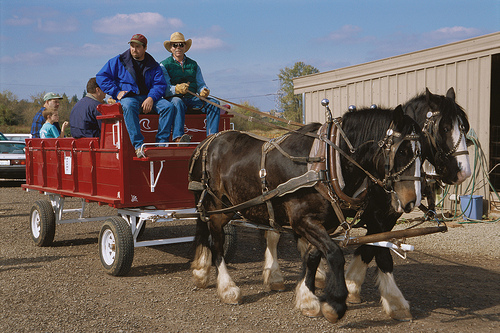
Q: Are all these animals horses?
A: Yes, all the animals are horses.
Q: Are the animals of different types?
A: No, all the animals are horses.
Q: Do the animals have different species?
A: No, all the animals are horses.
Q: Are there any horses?
A: Yes, there are horses.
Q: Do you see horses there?
A: Yes, there are horses.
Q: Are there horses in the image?
A: Yes, there are horses.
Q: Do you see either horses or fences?
A: Yes, there are horses.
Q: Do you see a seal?
A: No, there are no seals.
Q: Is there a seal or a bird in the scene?
A: No, there are no seals or birds.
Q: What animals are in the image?
A: The animals are horses.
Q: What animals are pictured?
A: The animals are horses.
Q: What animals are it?
A: The animals are horses.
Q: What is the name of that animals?
A: These are horses.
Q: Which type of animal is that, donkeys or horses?
A: These are horses.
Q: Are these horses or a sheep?
A: These are horses.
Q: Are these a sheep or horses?
A: These are horses.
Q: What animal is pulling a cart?
A: The horses are pulling a cart.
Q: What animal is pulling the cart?
A: The horses are pulling a cart.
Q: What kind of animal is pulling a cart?
A: The animals are horses.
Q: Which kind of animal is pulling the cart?
A: The animals are horses.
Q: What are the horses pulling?
A: The horses are pulling a cart.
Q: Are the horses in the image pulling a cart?
A: Yes, the horses are pulling a cart.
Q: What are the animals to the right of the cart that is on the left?
A: The animals are horses.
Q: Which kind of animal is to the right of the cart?
A: The animals are horses.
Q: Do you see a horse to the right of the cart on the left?
A: Yes, there are horses to the right of the cart.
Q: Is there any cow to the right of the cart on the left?
A: No, there are horses to the right of the cart.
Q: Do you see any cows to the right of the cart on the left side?
A: No, there are horses to the right of the cart.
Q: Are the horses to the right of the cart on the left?
A: Yes, the horses are to the right of the cart.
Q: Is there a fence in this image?
A: No, there are no fences.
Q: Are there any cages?
A: No, there are no cages.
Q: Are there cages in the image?
A: No, there are no cages.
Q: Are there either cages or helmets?
A: No, there are no cages or helmets.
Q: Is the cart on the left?
A: Yes, the cart is on the left of the image.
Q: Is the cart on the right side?
A: No, the cart is on the left of the image.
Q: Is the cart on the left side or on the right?
A: The cart is on the left of the image.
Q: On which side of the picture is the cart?
A: The cart is on the left of the image.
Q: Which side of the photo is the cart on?
A: The cart is on the left of the image.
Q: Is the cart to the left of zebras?
A: No, the cart is to the left of the horses.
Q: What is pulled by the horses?
A: The cart is pulled by the horses.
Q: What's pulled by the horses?
A: The cart is pulled by the horses.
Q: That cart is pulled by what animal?
A: The cart is pulled by the horses.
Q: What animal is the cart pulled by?
A: The cart is pulled by the horses.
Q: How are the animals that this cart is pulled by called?
A: The animals are horses.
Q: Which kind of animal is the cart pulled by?
A: The cart is pulled by the horses.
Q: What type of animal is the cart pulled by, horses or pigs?
A: The cart is pulled by horses.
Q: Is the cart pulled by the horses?
A: Yes, the cart is pulled by the horses.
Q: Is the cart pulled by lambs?
A: No, the cart is pulled by the horses.